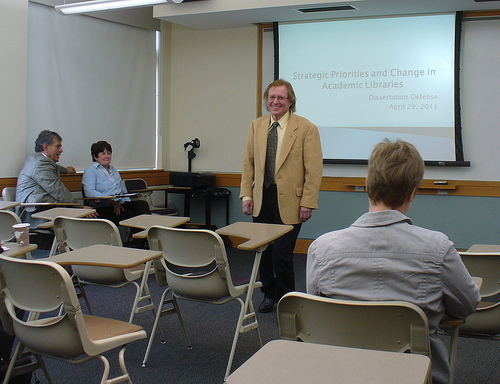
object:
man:
[231, 75, 328, 322]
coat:
[233, 110, 327, 230]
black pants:
[246, 181, 306, 299]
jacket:
[248, 112, 315, 218]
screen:
[276, 12, 464, 165]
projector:
[160, 162, 216, 189]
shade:
[26, 2, 156, 171]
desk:
[212, 220, 293, 248]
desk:
[223, 335, 431, 382]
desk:
[51, 243, 163, 265]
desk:
[117, 212, 190, 237]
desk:
[30, 205, 96, 217]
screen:
[260, 12, 480, 175]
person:
[242, 80, 312, 311]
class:
[15, 1, 489, 367]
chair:
[147, 227, 280, 338]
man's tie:
[264, 120, 279, 182]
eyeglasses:
[265, 95, 291, 104]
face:
[264, 89, 302, 124]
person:
[280, 129, 483, 353]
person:
[82, 137, 155, 241]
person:
[13, 127, 85, 247]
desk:
[3, 238, 166, 382]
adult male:
[237, 67, 324, 298]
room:
[58, 41, 460, 344]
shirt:
[254, 124, 311, 154]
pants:
[266, 188, 306, 298]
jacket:
[319, 197, 473, 330]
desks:
[0, 196, 498, 381]